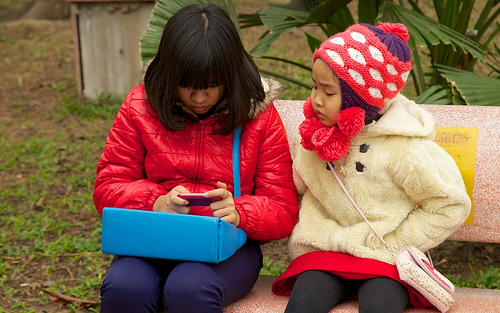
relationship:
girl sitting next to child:
[93, 3, 299, 312] [272, 21, 471, 313]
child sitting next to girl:
[272, 21, 471, 313] [93, 3, 299, 312]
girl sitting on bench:
[93, 3, 299, 312] [227, 99, 499, 311]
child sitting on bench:
[272, 21, 471, 313] [227, 99, 499, 311]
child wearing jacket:
[272, 21, 471, 313] [285, 92, 472, 267]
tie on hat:
[298, 96, 367, 164] [298, 19, 414, 159]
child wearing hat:
[272, 21, 471, 313] [298, 19, 414, 159]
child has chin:
[272, 21, 471, 313] [317, 117, 335, 126]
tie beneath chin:
[298, 96, 367, 164] [317, 117, 335, 126]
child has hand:
[272, 21, 471, 313] [382, 231, 400, 256]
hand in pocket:
[382, 231, 400, 256] [376, 228, 396, 248]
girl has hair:
[93, 3, 299, 312] [144, 3, 266, 136]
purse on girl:
[101, 128, 248, 262] [93, 3, 299, 312]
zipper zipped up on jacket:
[188, 120, 204, 215] [95, 82, 299, 240]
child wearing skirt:
[272, 21, 471, 313] [269, 252, 427, 312]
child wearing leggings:
[272, 21, 471, 313] [283, 269, 409, 311]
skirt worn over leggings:
[269, 252, 427, 312] [283, 269, 409, 311]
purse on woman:
[101, 128, 248, 262] [91, 4, 298, 312]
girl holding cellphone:
[93, 3, 299, 312] [178, 190, 217, 203]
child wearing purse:
[276, 3, 476, 309] [325, 161, 457, 311]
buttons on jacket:
[312, 138, 372, 178] [285, 92, 472, 267]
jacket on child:
[285, 92, 472, 267] [276, 3, 476, 309]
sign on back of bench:
[421, 117, 483, 235] [271, 91, 483, 256]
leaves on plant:
[395, 1, 474, 53] [132, 1, 484, 105]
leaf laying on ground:
[42, 280, 114, 310] [3, 21, 110, 310]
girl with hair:
[93, 4, 299, 313] [133, 1, 292, 141]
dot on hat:
[337, 45, 365, 66] [313, 15, 453, 120]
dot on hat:
[359, 58, 388, 88] [307, 10, 412, 108]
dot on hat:
[344, 28, 370, 44] [319, 0, 416, 120]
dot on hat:
[397, 69, 413, 88] [284, 4, 414, 114]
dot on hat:
[323, 30, 349, 50] [301, 10, 418, 114]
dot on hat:
[347, 47, 368, 65] [315, 17, 415, 117]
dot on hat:
[369, 67, 384, 82] [301, 10, 418, 114]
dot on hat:
[382, 80, 402, 93] [301, 10, 418, 114]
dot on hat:
[313, 45, 345, 69] [312, 15, 423, 106]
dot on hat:
[335, 66, 377, 91] [301, 10, 418, 114]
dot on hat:
[325, 49, 346, 68] [306, 18, 415, 132]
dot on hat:
[347, 47, 368, 65] [308, 19, 416, 112]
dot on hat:
[369, 67, 384, 82] [309, 18, 416, 124]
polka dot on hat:
[365, 85, 386, 103] [308, 19, 416, 112]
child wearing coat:
[272, 21, 471, 313] [292, 92, 476, 273]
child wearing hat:
[272, 21, 471, 313] [315, 17, 415, 117]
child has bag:
[272, 21, 471, 313] [391, 242, 457, 310]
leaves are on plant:
[411, 16, 441, 68] [388, 0, 498, 108]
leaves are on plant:
[394, 3, 498, 69] [335, 2, 498, 102]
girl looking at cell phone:
[93, 3, 299, 312] [172, 188, 225, 207]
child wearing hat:
[272, 21, 471, 313] [306, 18, 415, 132]